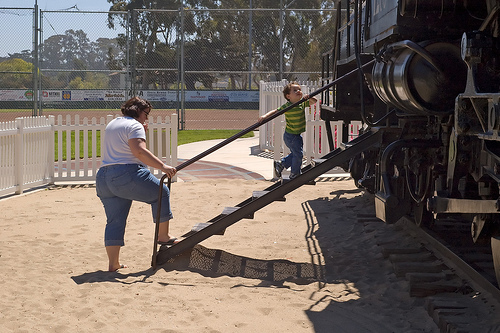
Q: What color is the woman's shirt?
A: White.